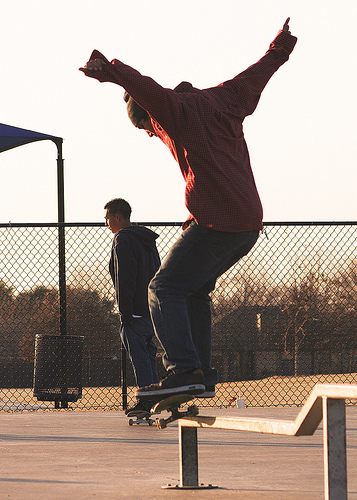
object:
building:
[211, 303, 357, 383]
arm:
[103, 54, 173, 122]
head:
[121, 90, 156, 137]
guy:
[74, 15, 299, 402]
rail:
[174, 381, 356, 500]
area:
[0, 406, 356, 499]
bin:
[30, 332, 84, 402]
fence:
[2, 217, 356, 413]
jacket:
[84, 29, 299, 237]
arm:
[220, 53, 284, 113]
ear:
[115, 213, 120, 221]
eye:
[106, 216, 110, 219]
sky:
[0, 0, 357, 287]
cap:
[123, 88, 147, 129]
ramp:
[176, 384, 356, 500]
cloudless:
[0, 0, 357, 222]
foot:
[132, 364, 205, 397]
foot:
[192, 381, 215, 397]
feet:
[134, 367, 205, 399]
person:
[104, 199, 162, 417]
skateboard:
[149, 392, 200, 431]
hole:
[292, 253, 299, 262]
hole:
[301, 258, 309, 266]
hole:
[315, 266, 324, 275]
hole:
[326, 253, 335, 262]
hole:
[294, 275, 303, 284]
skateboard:
[126, 407, 154, 427]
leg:
[147, 226, 224, 379]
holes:
[30, 329, 83, 401]